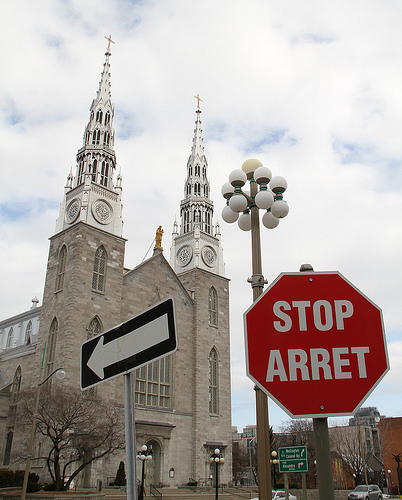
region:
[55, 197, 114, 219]
clock on a tower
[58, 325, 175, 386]
one way traffic sign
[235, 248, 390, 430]
stop sign on the pole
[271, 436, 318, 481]
green and white traffic sign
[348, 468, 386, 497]
car parked on the curb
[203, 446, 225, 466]
lights on the pole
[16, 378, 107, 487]
tree with not leaves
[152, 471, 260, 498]
steps in front of a church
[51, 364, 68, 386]
light on a pole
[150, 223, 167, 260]
statue on a building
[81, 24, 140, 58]
A cross in the photo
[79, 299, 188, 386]
A road sign in the photo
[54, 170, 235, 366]
Church in the photo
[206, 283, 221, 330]
A window in the photo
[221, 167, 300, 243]
Street lighting in the photo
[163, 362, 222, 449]
A building in the photo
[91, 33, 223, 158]
Two crosses on top of the building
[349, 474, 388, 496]
A car in the photo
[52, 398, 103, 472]
A tree in the photo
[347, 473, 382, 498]
Car parked in the background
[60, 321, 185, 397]
the arrow is white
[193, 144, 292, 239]
a pile of white lamps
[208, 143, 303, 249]
lights on the top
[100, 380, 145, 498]
a iron rod in road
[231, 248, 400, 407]
a red sign board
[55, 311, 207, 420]
a arrow towards left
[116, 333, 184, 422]
a part of front window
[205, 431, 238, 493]
a small iron stand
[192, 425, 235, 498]
a pole in the road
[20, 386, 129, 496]
a tree in th e road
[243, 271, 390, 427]
red board with white text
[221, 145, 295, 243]
a group of lights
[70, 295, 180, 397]
black sign with a white arrow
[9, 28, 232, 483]
tall light colored brick church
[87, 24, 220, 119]
two crosses at the top of the church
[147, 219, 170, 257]
religious statue on church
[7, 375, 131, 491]
tree with no leaves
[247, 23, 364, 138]
sky covered with large white clouds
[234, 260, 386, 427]
red and white stop sign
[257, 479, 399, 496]
two cars parked on the street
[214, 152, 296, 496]
street light with many round decorative lights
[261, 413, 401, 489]
red brick building in the background